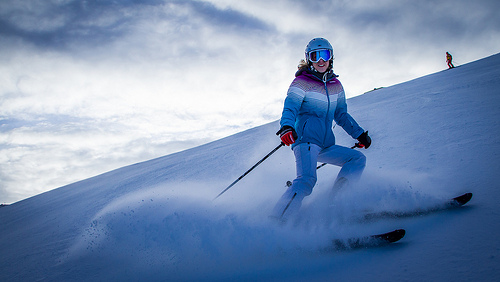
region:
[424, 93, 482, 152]
the snow is white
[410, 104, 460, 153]
the snow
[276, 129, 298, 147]
the women is wearing gloves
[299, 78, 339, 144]
a jacket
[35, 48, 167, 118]
the clouds are white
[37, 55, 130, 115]
the clouds in the sky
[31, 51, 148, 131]
the sky has clouds in it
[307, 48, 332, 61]
ski goggles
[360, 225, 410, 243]
a ski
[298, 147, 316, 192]
the women is wearing pants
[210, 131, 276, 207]
The left ski pole.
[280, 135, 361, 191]
The right ski pole.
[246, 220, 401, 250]
The left ski.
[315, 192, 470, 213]
The right ski.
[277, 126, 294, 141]
The left glove.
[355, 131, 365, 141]
The right glove.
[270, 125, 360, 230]
The pants the skier is wearing.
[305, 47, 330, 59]
The snow goggles the skier is wearing.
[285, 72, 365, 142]
The coat the skier is wearing.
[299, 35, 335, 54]
The blue helmet on the skier's head.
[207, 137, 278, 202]
the black pole in the mans hand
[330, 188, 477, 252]
the black skies on the feet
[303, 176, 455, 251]
the snow flying in the air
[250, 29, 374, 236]
the women stoping on the mountain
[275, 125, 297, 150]
the red glove in her hand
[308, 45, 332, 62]
the lens of the googles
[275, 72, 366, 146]
the jacket of the women on skies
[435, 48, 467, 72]
the skier on the mountain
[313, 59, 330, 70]
the smile on the womens face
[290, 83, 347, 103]
the white stripe on the jacket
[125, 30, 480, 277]
a woman sliding on a skis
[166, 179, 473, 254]
a pair of skis covered in snow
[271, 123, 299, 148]
a woman with red gloves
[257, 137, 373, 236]
a woman with blue pants for snow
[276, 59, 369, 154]
a woman with a white and blue jacket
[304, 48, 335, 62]
a woman with white goggles for snow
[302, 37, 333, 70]
a woman with a blue helmet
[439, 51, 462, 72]
a person standing with skis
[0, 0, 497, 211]
a cloud blue sky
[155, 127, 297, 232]
a woman holding a ski pole